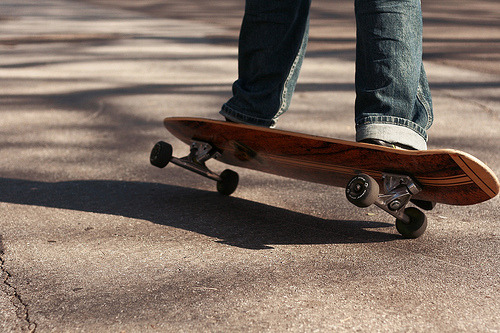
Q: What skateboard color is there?
A: Brown.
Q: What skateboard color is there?
A: Brown.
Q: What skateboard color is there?
A: Brown.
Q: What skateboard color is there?
A: Brown.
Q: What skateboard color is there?
A: Brown.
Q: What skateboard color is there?
A: Brown.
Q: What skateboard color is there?
A: Brown.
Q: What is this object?
A: Skateboard.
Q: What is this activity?
A: Skateboarding.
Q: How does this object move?
A: On wheels.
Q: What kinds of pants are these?
A: Blue jeans.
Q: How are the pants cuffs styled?
A: They are folded over.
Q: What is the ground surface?
A: Cement.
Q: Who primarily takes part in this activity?
A: Teenage boys.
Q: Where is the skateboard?
A: On the pavement.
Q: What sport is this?
A: Skateboarding.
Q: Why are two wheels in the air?
A: Skateboard is tilted.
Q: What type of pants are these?
A: Jeans.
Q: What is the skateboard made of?
A: Wood.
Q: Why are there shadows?
A: Sunny.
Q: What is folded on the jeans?
A: Cuffs.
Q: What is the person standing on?
A: Skateboard.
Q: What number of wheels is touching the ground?
A: 2.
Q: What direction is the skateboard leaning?
A: Right.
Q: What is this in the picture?
A: Feet on the board.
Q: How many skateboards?
A: 1.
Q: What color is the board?
A: Brown.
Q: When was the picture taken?
A: Daytime.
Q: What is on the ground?
A: Concrete.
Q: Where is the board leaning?
A: To the right.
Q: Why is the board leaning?
A: Balance.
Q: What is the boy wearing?
A: Jeans.